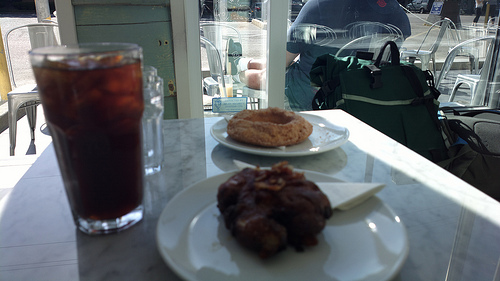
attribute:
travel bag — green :
[306, 36, 438, 160]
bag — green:
[304, 41, 441, 126]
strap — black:
[419, 73, 437, 103]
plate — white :
[223, 134, 350, 157]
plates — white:
[154, 105, 413, 279]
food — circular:
[226, 105, 312, 147]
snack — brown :
[222, 101, 316, 151]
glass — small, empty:
[141, 75, 161, 172]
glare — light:
[286, 17, 409, 54]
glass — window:
[283, 0, 498, 110]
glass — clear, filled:
[29, 40, 144, 234]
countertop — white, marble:
[27, 133, 499, 265]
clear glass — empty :
[142, 66, 160, 173]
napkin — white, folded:
[329, 179, 389, 204]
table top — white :
[204, 72, 499, 230]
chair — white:
[435, 7, 498, 103]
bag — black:
[308, 50, 443, 155]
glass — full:
[23, 38, 157, 233]